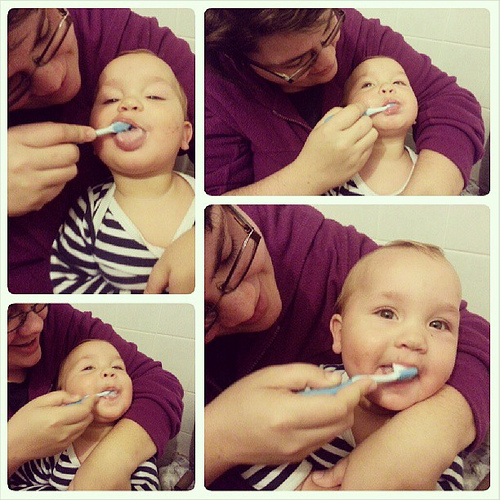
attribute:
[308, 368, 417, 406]
brush — white, close, short, blue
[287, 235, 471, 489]
baby — brown, close, looking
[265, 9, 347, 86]
glasses — thick, black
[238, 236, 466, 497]
child — small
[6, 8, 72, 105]
glasses — pair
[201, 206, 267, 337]
glasses — pair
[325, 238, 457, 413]
face — cute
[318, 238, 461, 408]
face — innocent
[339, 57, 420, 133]
face — lovely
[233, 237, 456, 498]
boy — cute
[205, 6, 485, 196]
woman — wide, white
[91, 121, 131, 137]
toothbrush — blue, white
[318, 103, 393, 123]
toothbrush — white, blue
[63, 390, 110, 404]
toothbrush — white, blue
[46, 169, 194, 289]
shirt — black, white, striped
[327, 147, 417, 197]
shirt — striped, black, white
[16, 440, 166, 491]
shirt — white, black, striped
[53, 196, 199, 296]
shirt — white , black 